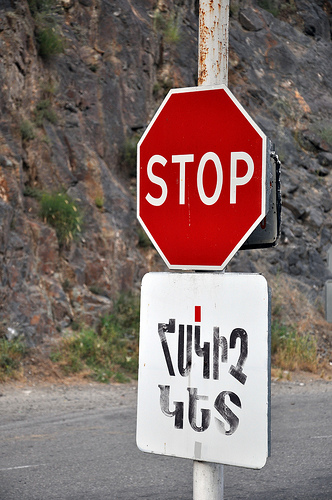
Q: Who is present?
A: Nobody.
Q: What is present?
A: A stop sign.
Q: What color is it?
A: Red.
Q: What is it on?
A: A road.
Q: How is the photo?
A: Clear.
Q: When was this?
A: Daytime.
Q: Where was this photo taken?
A: On a street.